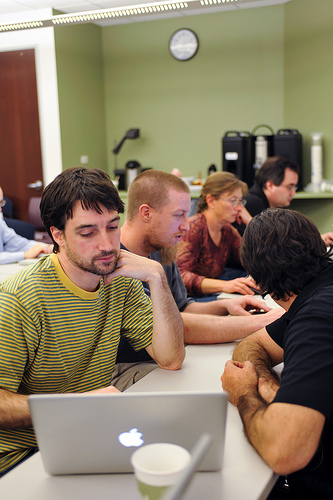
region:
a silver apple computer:
[27, 394, 227, 473]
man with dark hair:
[38, 169, 120, 272]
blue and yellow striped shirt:
[0, 261, 157, 452]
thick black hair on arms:
[230, 338, 278, 449]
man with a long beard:
[120, 166, 191, 267]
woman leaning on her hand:
[196, 170, 254, 230]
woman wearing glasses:
[201, 173, 244, 224]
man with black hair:
[255, 153, 298, 208]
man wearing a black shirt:
[232, 209, 331, 498]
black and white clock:
[167, 25, 198, 62]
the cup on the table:
[124, 440, 192, 499]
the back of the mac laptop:
[30, 393, 225, 476]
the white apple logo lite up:
[112, 422, 147, 448]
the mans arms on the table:
[215, 337, 320, 471]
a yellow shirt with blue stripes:
[1, 260, 161, 406]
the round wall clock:
[163, 23, 208, 60]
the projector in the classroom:
[107, 114, 154, 192]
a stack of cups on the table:
[302, 130, 331, 192]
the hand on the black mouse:
[230, 276, 264, 300]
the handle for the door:
[26, 179, 42, 188]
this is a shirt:
[0, 238, 173, 470]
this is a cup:
[120, 441, 198, 498]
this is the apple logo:
[116, 421, 159, 459]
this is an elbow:
[263, 455, 316, 485]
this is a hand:
[211, 359, 258, 396]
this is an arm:
[206, 357, 329, 482]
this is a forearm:
[232, 382, 283, 448]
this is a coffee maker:
[208, 119, 307, 194]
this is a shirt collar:
[22, 216, 121, 303]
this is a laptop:
[17, 374, 245, 488]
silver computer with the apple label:
[26, 390, 227, 473]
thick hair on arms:
[226, 344, 281, 427]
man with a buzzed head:
[123, 167, 189, 266]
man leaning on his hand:
[36, 168, 184, 368]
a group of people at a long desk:
[11, 150, 331, 485]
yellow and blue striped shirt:
[7, 257, 152, 385]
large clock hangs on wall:
[169, 24, 200, 60]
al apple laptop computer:
[29, 390, 227, 474]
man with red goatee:
[124, 164, 191, 264]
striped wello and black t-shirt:
[0, 250, 153, 475]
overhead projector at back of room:
[107, 121, 152, 190]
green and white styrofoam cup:
[131, 439, 195, 497]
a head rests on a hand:
[191, 173, 254, 232]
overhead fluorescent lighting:
[0, 0, 195, 38]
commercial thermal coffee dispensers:
[220, 111, 303, 199]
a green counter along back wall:
[107, 188, 327, 197]